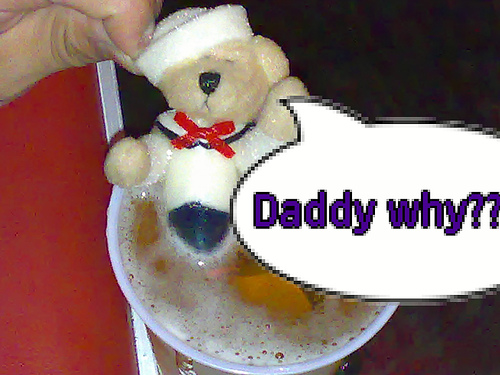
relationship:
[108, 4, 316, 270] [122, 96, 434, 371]
bear in cup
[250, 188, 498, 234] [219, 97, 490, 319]
quotation with outline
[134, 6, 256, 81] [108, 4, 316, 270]
cap of bear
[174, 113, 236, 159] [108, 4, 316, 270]
ribbon of bear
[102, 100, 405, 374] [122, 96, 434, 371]
drink in cup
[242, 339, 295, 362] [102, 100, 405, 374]
bubble of drink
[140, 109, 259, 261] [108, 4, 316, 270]
sailor uniform of bear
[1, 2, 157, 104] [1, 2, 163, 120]
fingers of person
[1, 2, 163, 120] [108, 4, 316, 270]
person holding bear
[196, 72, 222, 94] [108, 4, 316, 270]
nose of bear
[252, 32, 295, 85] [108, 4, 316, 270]
ear of bear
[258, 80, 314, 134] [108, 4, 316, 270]
hand of bear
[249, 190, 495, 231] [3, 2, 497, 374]
letter on picture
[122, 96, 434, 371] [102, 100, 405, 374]
cup full of drink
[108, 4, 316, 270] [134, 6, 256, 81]
bear wearing hat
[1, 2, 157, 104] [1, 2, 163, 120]
hand of person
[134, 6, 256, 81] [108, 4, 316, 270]
hat on bear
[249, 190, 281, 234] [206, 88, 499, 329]
letter in bubble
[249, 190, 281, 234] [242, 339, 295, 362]
letter in bubble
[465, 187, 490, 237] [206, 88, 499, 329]
question mark in bubble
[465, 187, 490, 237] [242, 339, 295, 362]
question mark in bubble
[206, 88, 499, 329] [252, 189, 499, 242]
bubble with text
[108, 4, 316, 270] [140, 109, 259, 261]
bear with sailor outfit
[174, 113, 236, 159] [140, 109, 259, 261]
bow adorning outfit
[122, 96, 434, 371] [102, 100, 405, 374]
cup with drink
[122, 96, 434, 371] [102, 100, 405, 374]
cup of drink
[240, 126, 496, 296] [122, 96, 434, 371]
bubble of cup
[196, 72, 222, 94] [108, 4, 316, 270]
nose on bear